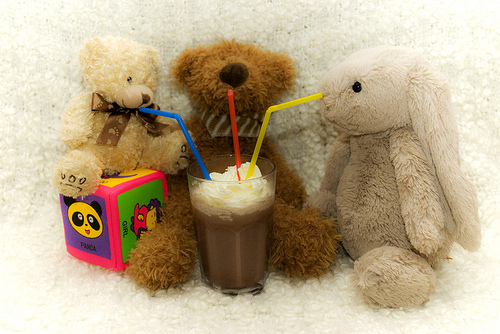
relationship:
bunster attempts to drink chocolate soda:
[316, 52, 483, 309] [187, 142, 278, 298]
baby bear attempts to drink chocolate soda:
[54, 36, 192, 198] [187, 142, 278, 298]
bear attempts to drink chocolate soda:
[121, 28, 346, 304] [187, 142, 278, 298]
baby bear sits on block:
[54, 36, 192, 198] [63, 165, 169, 272]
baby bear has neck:
[54, 36, 192, 198] [85, 83, 111, 105]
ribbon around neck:
[90, 93, 169, 151] [85, 83, 111, 105]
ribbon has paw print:
[90, 93, 169, 151] [93, 93, 103, 108]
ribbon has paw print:
[90, 93, 169, 151] [106, 125, 120, 136]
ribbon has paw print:
[90, 93, 169, 151] [112, 113, 125, 126]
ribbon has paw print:
[90, 93, 169, 151] [87, 93, 107, 114]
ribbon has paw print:
[90, 93, 169, 151] [104, 98, 115, 113]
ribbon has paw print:
[90, 93, 169, 151] [146, 122, 155, 131]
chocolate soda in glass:
[187, 142, 278, 298] [187, 154, 276, 291]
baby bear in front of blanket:
[54, 36, 192, 198] [1, 1, 499, 333]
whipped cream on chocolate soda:
[192, 159, 274, 212] [187, 142, 278, 298]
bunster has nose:
[316, 52, 483, 309] [315, 86, 333, 108]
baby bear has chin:
[54, 36, 192, 198] [127, 104, 145, 114]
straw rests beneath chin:
[136, 103, 215, 180] [127, 104, 145, 114]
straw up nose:
[244, 94, 320, 178] [315, 86, 333, 108]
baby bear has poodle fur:
[54, 36, 192, 198] [48, 30, 198, 202]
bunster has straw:
[316, 52, 483, 309] [244, 94, 320, 178]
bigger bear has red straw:
[125, 28, 349, 297] [219, 88, 247, 186]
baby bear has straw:
[45, 29, 197, 203] [139, 107, 213, 181]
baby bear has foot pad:
[45, 29, 197, 203] [58, 170, 87, 195]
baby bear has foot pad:
[45, 29, 197, 203] [175, 140, 193, 169]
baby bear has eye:
[45, 29, 197, 203] [126, 74, 133, 84]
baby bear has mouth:
[45, 29, 197, 203] [119, 98, 147, 113]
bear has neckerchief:
[126, 41, 340, 289] [191, 104, 275, 144]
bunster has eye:
[303, 38, 486, 316] [349, 77, 365, 97]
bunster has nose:
[303, 38, 486, 316] [315, 86, 333, 108]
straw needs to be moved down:
[243, 93, 321, 178] [315, 112, 350, 132]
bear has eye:
[126, 41, 340, 289] [219, 54, 229, 62]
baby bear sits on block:
[45, 29, 197, 203] [63, 165, 169, 277]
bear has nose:
[126, 41, 340, 289] [217, 60, 250, 90]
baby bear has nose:
[45, 29, 197, 203] [138, 90, 154, 108]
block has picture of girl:
[63, 165, 169, 277] [130, 197, 161, 239]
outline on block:
[63, 166, 166, 270] [63, 165, 169, 277]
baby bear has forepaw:
[45, 29, 197, 203] [56, 118, 93, 148]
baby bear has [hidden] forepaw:
[45, 29, 197, 203] [149, 115, 178, 137]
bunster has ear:
[303, 38, 486, 316] [407, 62, 483, 257]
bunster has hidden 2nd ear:
[303, 38, 486, 316] [410, 124, 413, 130]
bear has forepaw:
[126, 41, 340, 289] [274, 169, 309, 208]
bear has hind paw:
[126, 41, 340, 289] [125, 226, 199, 294]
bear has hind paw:
[126, 41, 340, 289] [267, 203, 339, 281]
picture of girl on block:
[127, 197, 164, 244] [63, 165, 169, 277]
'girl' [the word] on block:
[118, 217, 130, 243] [63, 165, 169, 277]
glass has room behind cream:
[187, 154, 276, 291] [187, 152, 277, 215]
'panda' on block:
[63, 195, 108, 242] [63, 165, 169, 277]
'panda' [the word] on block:
[78, 238, 99, 256] [63, 165, 169, 277]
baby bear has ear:
[45, 29, 197, 203] [73, 29, 108, 76]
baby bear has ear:
[45, 29, 197, 203] [144, 47, 165, 76]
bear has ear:
[126, 41, 340, 289] [260, 43, 300, 100]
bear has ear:
[126, 41, 340, 289] [169, 42, 206, 94]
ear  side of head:
[260, 43, 300, 100] [255, 29, 300, 116]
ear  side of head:
[169, 42, 206, 94] [165, 41, 217, 114]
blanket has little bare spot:
[1, 1, 499, 333] [303, 11, 310, 35]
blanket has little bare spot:
[1, 1, 499, 333] [128, 12, 148, 36]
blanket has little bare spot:
[1, 1, 499, 333] [246, 24, 284, 49]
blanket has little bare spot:
[1, 1, 499, 333] [48, 95, 58, 113]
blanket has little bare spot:
[1, 1, 499, 333] [25, 172, 53, 211]